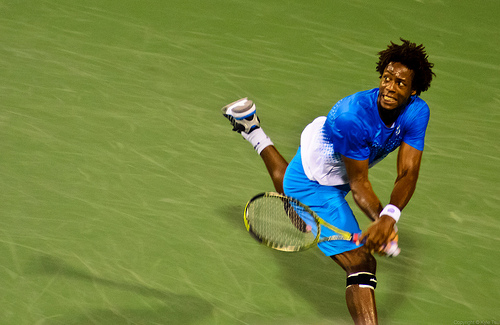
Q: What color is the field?
A: Green.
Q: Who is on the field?
A: The man.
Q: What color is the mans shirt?
A: Blue.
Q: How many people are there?
A: One.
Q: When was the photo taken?
A: Day time.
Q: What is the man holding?
A: The racket.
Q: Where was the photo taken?
A: At a tennis match.